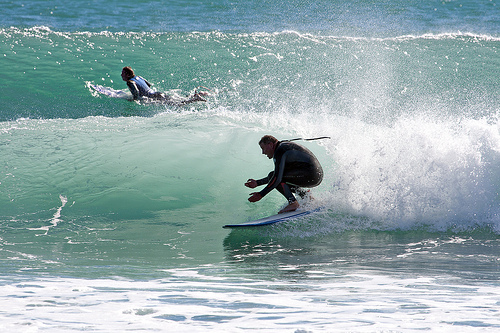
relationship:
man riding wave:
[245, 135, 324, 215] [0, 103, 496, 224]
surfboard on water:
[222, 208, 316, 228] [168, 237, 410, 300]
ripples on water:
[0, 216, 499, 324] [33, 151, 408, 316]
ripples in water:
[0, 216, 499, 324] [340, 235, 445, 307]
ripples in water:
[0, 216, 499, 324] [0, 0, 499, 330]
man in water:
[120, 66, 209, 105] [0, 0, 499, 330]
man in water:
[245, 135, 324, 215] [0, 0, 499, 330]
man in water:
[112, 63, 212, 108] [334, 64, 431, 129]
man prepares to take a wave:
[245, 135, 324, 215] [4, 25, 499, 125]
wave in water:
[0, 25, 500, 224] [0, 0, 499, 330]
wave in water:
[0, 25, 497, 113] [0, 0, 499, 330]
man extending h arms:
[245, 135, 324, 215] [240, 156, 286, 206]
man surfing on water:
[246, 135, 356, 202] [30, 110, 221, 299]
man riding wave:
[245, 135, 324, 215] [332, 134, 453, 204]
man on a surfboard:
[245, 135, 324, 215] [224, 201, 324, 231]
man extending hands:
[245, 135, 324, 215] [221, 171, 255, 204]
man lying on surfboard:
[120, 66, 209, 105] [85, 78, 132, 98]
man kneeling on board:
[245, 135, 324, 215] [222, 205, 326, 227]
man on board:
[120, 66, 209, 105] [84, 79, 135, 104]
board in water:
[84, 79, 135, 104] [0, 0, 499, 330]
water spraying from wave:
[217, 70, 499, 217] [4, 25, 499, 125]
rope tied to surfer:
[277, 135, 332, 143] [243, 133, 324, 213]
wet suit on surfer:
[237, 129, 344, 243] [256, 120, 292, 200]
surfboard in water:
[216, 207, 320, 227] [0, 0, 499, 330]